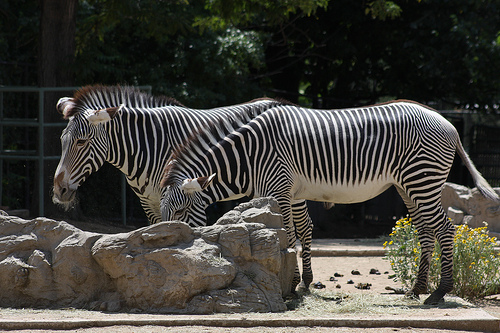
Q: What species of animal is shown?
A: Zebra.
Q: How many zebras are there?
A: Two.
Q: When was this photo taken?
A: Day time.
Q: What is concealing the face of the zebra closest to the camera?
A: A rock.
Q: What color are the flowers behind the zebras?
A: Yellow.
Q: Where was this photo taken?
A: A zoo.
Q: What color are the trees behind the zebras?
A: Green.